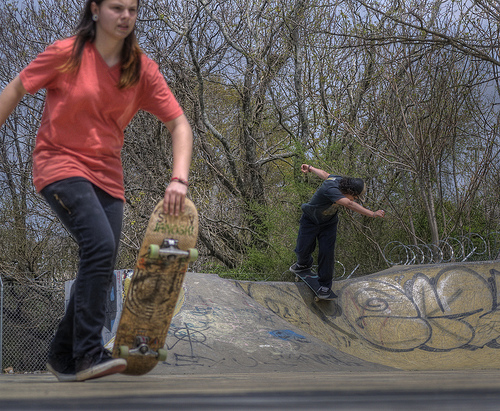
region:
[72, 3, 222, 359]
The girl is lifting the skateboard.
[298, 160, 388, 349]
The man is riding the skateboard.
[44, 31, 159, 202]
The girl is wearing a orange t-shirt.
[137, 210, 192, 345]
The skateboard has graffiti on it.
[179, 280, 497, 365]
The wall has a bunch of graffiti written on it.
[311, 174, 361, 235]
The boy has on a black shirt.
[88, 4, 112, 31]
The girl is wearing a earring.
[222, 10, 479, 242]
The trees are behind the fence.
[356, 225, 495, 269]
The fence has wire on top.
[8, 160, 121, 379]
The girl is wearing black pants.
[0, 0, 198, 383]
the girl is skateboarding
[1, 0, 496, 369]
the trees don't have leaves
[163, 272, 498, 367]
the ground has graffiti on it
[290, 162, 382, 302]
the boy is skateboarding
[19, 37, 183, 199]
the girl has a red shirt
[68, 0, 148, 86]
the girl has long hair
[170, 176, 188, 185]
the girl has a bracelet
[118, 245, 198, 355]
the skateboard has green wheels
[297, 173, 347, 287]
the boy is wearing blue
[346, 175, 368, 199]
the boy is wearing a hat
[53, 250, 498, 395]
Graffiti on skateboard ramp.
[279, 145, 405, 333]
Boy on skateboard ramp.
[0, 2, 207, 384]
Girl is holding skateboard.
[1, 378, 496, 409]
Street is dry.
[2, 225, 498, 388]
Fence behind skateboard ramp.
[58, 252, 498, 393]
Ramp is made of concrete.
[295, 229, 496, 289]
Barbed wire on top of fence.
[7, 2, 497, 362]
Tree limbs are bare.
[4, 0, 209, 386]
Girl is wearing blue jens.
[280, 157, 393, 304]
Boy's arms are raised.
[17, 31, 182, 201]
the girl is wearing a pink shirt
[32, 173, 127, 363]
the girl is wearing dark jeans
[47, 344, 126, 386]
the girls is wearing black shoes with white soles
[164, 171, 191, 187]
the girl is wearing a bracelet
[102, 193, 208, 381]
the girl has a brown skateboard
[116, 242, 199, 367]
the skateboard has light yellow wheels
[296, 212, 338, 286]
the boy is wearing jeans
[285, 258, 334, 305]
the boy has black shoes with white laces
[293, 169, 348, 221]
the boy is wearing a black shirt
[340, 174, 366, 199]
the boy is wearing a black hat backwards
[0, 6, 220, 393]
Girl holding skateboard with her left hand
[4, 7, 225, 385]
girl wearing an orange shirt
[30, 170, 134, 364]
Blue pants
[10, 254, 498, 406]
Skateboard track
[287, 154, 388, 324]
Boy skating down the trail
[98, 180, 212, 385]
Skateboard is yellow with green wheels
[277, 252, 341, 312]
Skateboard is black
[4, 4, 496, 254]
Trees without leaves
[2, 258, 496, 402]
track is grey and yellow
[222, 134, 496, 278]
Green bushes behind the boy